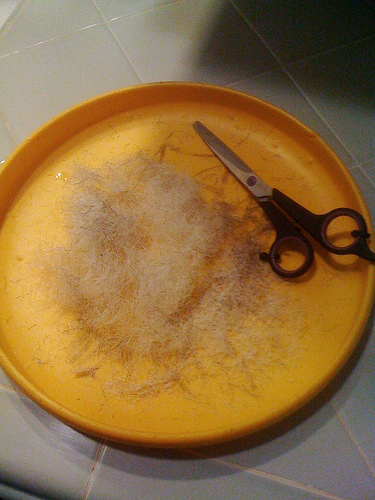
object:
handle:
[255, 188, 375, 280]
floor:
[0, 2, 375, 500]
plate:
[1, 80, 375, 459]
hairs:
[44, 130, 293, 387]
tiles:
[107, 0, 280, 88]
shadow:
[193, 4, 374, 112]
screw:
[247, 177, 257, 189]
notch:
[258, 248, 269, 262]